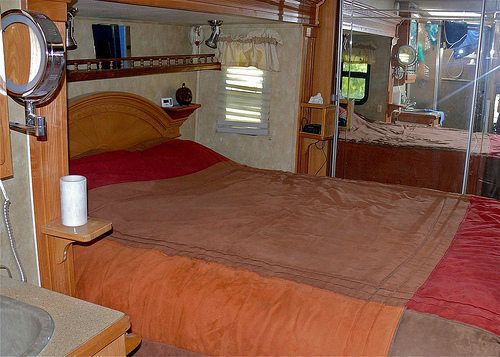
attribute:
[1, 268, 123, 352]
countertop — clear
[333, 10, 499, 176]
mirror — vanity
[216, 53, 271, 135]
window — small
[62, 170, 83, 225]
candle — white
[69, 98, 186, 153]
headboard — wooden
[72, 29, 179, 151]
headboard — wooden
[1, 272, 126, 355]
wood edge — wooden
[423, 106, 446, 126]
rag — blue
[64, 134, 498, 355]
blanket — brown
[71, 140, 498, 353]
cover — bed, multi color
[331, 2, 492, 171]
mirror — large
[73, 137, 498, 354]
bedspread — red, orange, brown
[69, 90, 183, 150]
head board — brown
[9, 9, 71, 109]
mirror — silver, round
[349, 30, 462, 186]
mirror — vanity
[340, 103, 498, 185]
bed — reflected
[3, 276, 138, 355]
sink — empty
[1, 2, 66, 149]
mirror — retractable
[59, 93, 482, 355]
bed — neatly made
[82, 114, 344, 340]
bedspread — orange, red, brown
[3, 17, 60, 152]
mirror — round